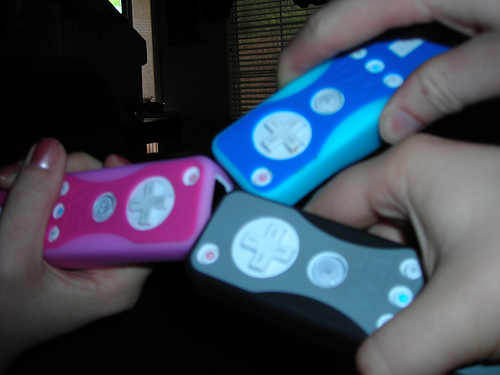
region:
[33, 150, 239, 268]
A pink controller with white buttons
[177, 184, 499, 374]
A grey and black controller with white buttons.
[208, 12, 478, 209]
A blue controller with white buttons.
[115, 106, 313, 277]
All three controllers have a large white button on the top.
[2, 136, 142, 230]
The person holding the pink controller is wearing light pink nail polish.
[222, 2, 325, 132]
The window has blinds on it.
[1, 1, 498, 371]
Three people holding controllers.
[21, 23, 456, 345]
The controllers are for a video game console.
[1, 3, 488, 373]
the room is dark.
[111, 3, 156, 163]
light is coming in through another door.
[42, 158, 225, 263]
Pink and white game controller.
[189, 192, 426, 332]
Gray and white game controller.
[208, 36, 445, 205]
Blue and white game controller.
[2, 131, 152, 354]
Female hand with pink nail polish.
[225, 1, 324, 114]
Wooden slated blinds.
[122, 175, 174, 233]
Game controller button with an cross.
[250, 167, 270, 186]
Game controller red and white power button.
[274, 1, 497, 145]
Person's hand holding game controller.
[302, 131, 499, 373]
Human hand holding gray game controller.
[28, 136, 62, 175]
Finger nail painted with pink polish.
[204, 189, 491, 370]
black casing on the wii remote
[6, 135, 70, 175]
pink nail polish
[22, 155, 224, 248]
pink casing on the wii remote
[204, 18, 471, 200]
blue casing on the wii remote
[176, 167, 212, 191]
on and off button on the remote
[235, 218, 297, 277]
directional keys of the remote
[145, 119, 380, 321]
the remotes are touching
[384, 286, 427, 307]
button is lit up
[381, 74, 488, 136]
thumb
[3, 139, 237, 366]
A hand is holding a pink remote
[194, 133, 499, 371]
a hand is holding a grey and black remote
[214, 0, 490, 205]
a hand is holding a blue remote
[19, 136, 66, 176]
the fingernails are painted pink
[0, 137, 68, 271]
the thumb is on top of the remote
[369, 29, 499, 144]
the thumb is on the side of the remote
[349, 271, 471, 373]
the thumb is wrapped around the remote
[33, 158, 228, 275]
the pink remote is touching the blue remote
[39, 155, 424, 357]
the pink remote is touching the grey remote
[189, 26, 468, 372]
the blue remote is touching the grey remote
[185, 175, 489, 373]
Remote control to play video games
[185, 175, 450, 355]
Remote control has buttons on tan surface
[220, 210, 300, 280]
Cross button is white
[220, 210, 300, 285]
Cross button is over a white circle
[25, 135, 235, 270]
Remote control is pink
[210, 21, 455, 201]
Remote control is is blue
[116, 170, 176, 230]
Cross button is over white circle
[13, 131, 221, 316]
Game control on a hand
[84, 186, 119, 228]
Round button in the center